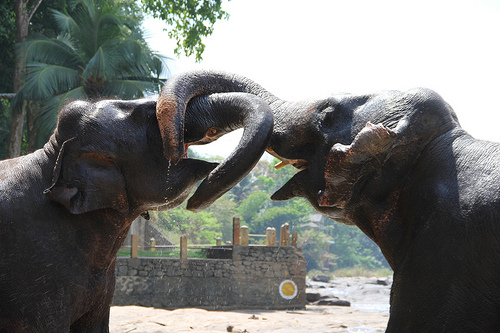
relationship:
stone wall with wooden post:
[141, 259, 300, 315] [227, 212, 246, 245]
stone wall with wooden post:
[141, 259, 300, 315] [277, 220, 294, 251]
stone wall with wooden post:
[141, 259, 300, 315] [291, 229, 300, 251]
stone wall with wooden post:
[141, 259, 300, 315] [179, 234, 191, 265]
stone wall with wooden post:
[141, 259, 300, 315] [127, 230, 147, 266]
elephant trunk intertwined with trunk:
[154, 69, 284, 165] [166, 89, 270, 212]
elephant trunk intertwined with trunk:
[154, 69, 284, 165] [155, 91, 274, 211]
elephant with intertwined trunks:
[155, 66, 499, 331] [155, 67, 326, 216]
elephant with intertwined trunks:
[1, 90, 273, 330] [155, 67, 326, 216]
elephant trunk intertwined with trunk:
[154, 69, 284, 165] [172, 85, 279, 207]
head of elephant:
[34, 76, 266, 249] [1, 90, 273, 330]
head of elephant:
[155, 47, 470, 239] [155, 66, 499, 331]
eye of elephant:
[317, 108, 339, 129] [155, 66, 499, 331]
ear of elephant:
[44, 131, 129, 216] [19, 16, 290, 331]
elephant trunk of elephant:
[154, 69, 284, 165] [1, 86, 201, 332]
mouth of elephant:
[259, 144, 311, 201] [196, 64, 495, 304]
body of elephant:
[2, 85, 273, 330] [1, 90, 273, 330]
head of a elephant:
[34, 91, 273, 227] [1, 90, 273, 330]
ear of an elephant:
[37, 136, 134, 223] [1, 90, 273, 330]